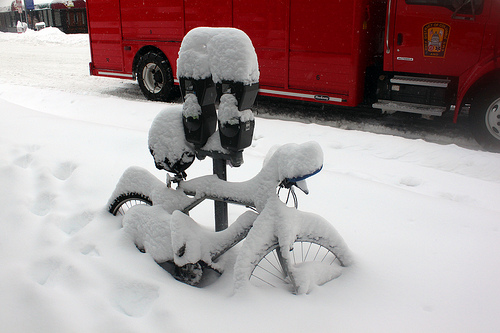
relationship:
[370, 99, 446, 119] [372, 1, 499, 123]
silver steps to truck cab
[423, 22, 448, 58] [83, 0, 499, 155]
emblem on red truck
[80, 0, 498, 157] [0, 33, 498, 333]
red truck on road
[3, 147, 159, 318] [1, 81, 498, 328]
foot prints by snow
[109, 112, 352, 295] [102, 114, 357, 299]
snow covered bike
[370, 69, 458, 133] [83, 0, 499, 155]
silver steps leading into red truck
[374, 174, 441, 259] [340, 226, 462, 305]
road covered in snow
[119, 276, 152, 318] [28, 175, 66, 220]
footprints in snow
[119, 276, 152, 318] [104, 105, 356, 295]
footprints beside bicycle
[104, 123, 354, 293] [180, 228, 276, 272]
bicycle covered snow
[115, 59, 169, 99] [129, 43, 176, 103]
chains on tire